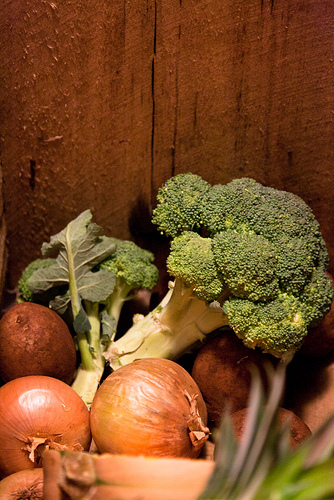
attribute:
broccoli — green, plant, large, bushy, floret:
[139, 174, 333, 355]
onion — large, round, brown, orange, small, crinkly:
[82, 355, 245, 498]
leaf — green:
[42, 201, 99, 320]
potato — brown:
[12, 300, 68, 363]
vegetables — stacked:
[15, 170, 313, 497]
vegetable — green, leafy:
[59, 234, 136, 390]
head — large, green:
[152, 175, 328, 302]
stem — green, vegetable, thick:
[99, 285, 214, 366]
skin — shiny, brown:
[113, 389, 176, 427]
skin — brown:
[16, 301, 41, 351]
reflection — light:
[122, 382, 154, 414]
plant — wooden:
[22, 30, 301, 201]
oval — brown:
[20, 148, 49, 189]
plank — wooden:
[5, 6, 331, 246]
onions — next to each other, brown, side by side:
[13, 365, 207, 461]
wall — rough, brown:
[6, 5, 333, 203]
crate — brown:
[18, 14, 311, 201]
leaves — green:
[212, 428, 326, 492]